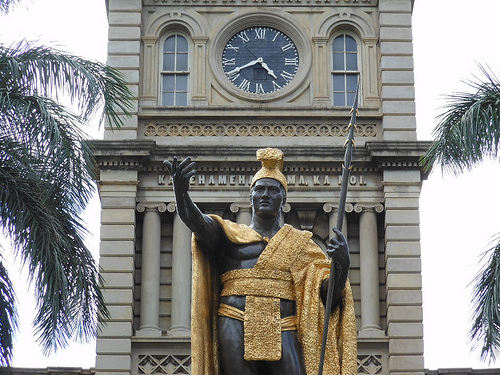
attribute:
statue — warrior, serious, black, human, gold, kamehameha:
[153, 73, 379, 375]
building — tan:
[94, 1, 435, 373]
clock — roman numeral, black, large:
[214, 12, 305, 99]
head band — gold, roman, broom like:
[247, 143, 293, 193]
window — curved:
[331, 28, 361, 107]